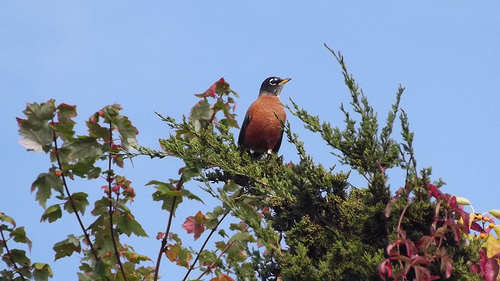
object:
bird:
[227, 76, 295, 162]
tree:
[0, 78, 283, 281]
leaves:
[12, 100, 58, 154]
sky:
[0, 0, 498, 280]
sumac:
[374, 179, 499, 281]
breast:
[251, 98, 284, 126]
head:
[259, 72, 290, 95]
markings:
[271, 79, 272, 81]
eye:
[268, 80, 280, 84]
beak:
[277, 75, 292, 88]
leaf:
[60, 136, 105, 178]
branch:
[152, 79, 232, 280]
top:
[107, 44, 419, 159]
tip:
[286, 78, 292, 81]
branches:
[181, 189, 245, 280]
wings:
[236, 110, 254, 150]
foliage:
[410, 262, 433, 280]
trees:
[151, 43, 497, 280]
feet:
[264, 149, 273, 161]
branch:
[153, 111, 345, 240]